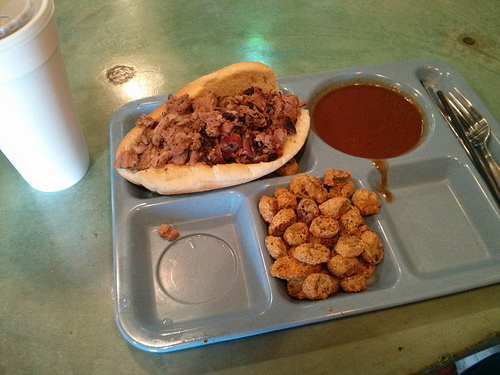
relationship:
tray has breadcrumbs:
[99, 55, 499, 349] [256, 172, 386, 306]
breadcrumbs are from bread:
[256, 172, 386, 306] [136, 164, 256, 194]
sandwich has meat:
[104, 62, 310, 186] [105, 92, 306, 168]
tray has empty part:
[99, 55, 499, 349] [399, 169, 491, 285]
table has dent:
[69, 9, 181, 86] [109, 62, 131, 86]